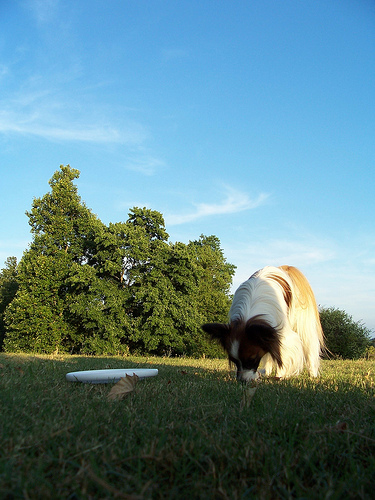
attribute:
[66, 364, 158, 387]
dog toy — white 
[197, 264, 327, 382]
dog — white, brown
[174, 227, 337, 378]
dog — small, furry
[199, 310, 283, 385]
head — bent down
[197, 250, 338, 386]
dog — standing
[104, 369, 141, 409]
leaf — brown 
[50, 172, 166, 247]
trees — Green 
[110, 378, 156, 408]
leaf — dead 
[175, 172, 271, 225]
clouds — are sparse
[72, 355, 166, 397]
white frisbee — is white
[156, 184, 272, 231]
cloud — thin, white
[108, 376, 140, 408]
leaf — dead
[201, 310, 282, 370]
fur — is brown